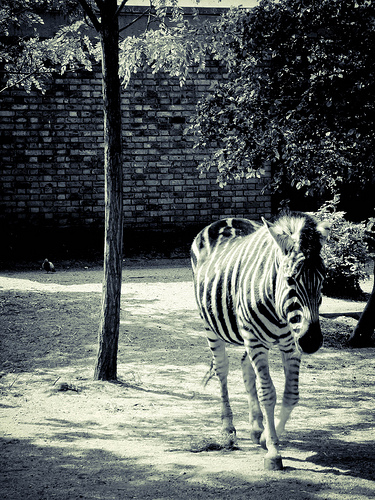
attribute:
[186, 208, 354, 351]
zebra — walking, looking, mane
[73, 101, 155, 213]
tree — skinny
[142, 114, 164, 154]
wall — brick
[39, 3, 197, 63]
sun — shining